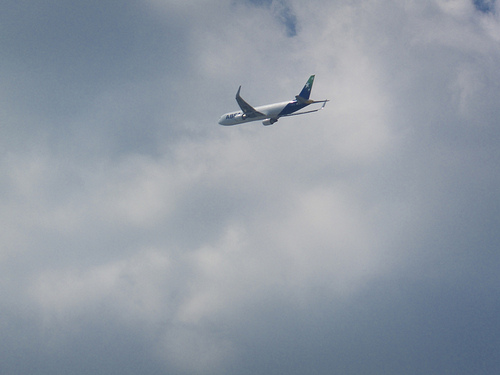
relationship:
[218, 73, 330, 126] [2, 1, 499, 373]
airplane in sky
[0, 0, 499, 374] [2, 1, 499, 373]
clouds in sky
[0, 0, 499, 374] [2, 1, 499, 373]
clouds are in sky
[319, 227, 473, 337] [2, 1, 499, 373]
cloud in sky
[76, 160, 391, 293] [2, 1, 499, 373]
clouds in sky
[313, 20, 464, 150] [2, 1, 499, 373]
clouds in sky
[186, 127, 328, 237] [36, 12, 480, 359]
clouds in sky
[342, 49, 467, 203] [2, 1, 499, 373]
clouds in sky